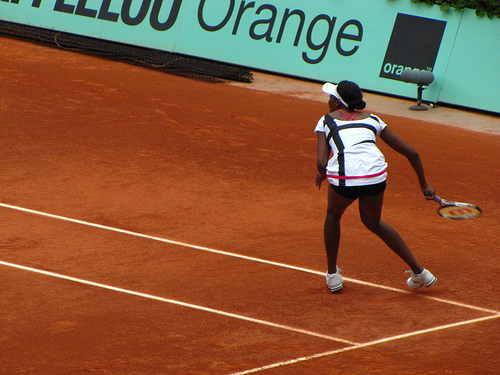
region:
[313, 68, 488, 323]
woman playing tennis on court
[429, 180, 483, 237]
tennis racket in woman's hand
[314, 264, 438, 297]
tennis shoes on woman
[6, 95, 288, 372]
orange tennis court woman plays on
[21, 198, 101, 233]
white markings on court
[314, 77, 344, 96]
white visor on woman's head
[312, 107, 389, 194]
athletic outfit worn by woman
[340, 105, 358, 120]
red straps on athletic outfit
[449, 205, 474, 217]
designer logo on tennis racket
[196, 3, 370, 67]
lettering on signage surrounding court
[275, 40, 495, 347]
tennis player near corner of court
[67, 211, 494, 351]
clay court under player's feet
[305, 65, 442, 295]
player bending forward with turned head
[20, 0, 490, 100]
advertisement on blue slanted panel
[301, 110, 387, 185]
black and red stripes over white dress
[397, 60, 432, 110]
black cylinder on stand at court edge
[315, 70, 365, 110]
white visor around pulled-back hair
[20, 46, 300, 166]
footprints on dark clay ground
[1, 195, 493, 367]
white lines showing borders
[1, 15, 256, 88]
black tarp rolled to edge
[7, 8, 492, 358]
woman playing tennis on a clay tennis court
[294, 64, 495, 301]
woman holding a tennis racquet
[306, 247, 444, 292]
white tennis shoes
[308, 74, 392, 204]
red, white, and black tennis suit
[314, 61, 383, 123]
woman wearing a white tennis visor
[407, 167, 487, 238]
red, white, and black tennis racquet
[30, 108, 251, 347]
red clay tennis court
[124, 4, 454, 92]
teal tennis wall with black words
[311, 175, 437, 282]
legs of a woman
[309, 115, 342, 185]
arm of a woman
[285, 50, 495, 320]
woman wearing a visor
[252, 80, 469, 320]
woman wearing white shirt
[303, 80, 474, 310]
woman wearing black shorts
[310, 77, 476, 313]
woman wearing white shoes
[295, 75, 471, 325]
woman holding a racket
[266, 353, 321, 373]
white line on a court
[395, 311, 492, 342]
white line on court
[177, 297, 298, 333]
white line on court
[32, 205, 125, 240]
white line on court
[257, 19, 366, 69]
sign near a court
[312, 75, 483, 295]
black woman playing tennis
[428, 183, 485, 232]
tennis racket with Wilson logo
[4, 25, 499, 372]
red clay tennis court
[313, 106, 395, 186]
red, white and black tennis dress worn by woman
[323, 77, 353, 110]
tennis visor hat worn by tennis player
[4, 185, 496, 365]
white chalk lines indicating game points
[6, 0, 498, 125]
aqua wall with black letting advertising sponsors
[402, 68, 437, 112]
small black ground lamp beside court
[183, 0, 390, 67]
black letters spelling Orange on blue sign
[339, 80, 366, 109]
woman has black hair worn in bun